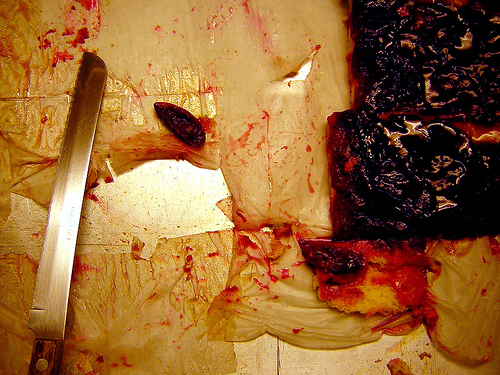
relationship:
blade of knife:
[10, 46, 112, 338] [23, 46, 108, 373]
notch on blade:
[29, 298, 46, 317] [25, 46, 112, 338]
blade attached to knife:
[25, 46, 112, 338] [23, 46, 108, 373]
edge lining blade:
[22, 49, 86, 336] [25, 46, 112, 338]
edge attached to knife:
[22, 49, 82, 335] [11, 53, 117, 373]